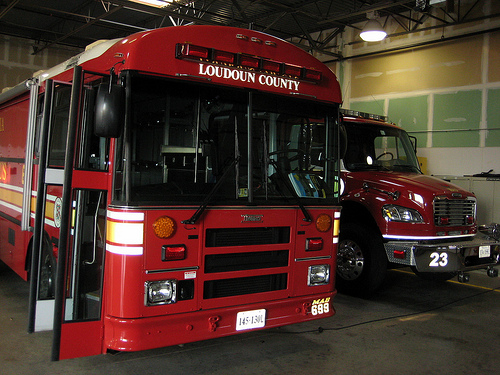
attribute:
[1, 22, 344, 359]
truck — parked, red, emergency vehicle, fire apparatus, vehicle, large, for  passengers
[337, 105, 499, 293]
truck — parked, red, emergency vehicle, fire apparatus, vehicle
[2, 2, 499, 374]
shed — fire station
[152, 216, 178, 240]
light — small, orange, emergency light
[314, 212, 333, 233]
light — emergency light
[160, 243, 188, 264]
light — emergency light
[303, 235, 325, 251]
light — emergency light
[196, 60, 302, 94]
letters — white, displayed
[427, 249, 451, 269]
number — 23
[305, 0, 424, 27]
rod — iron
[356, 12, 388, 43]
light — attached, on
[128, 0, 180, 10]
light — on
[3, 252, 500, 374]
floor — grey, partly road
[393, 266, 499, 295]
line — yellow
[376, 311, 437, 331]
line — yellow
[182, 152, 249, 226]
windshield wiper — black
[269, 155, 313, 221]
windshield wiper — black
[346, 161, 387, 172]
windshield wiper — black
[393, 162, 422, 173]
windshield wiper — black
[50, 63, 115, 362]
door — open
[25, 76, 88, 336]
door — open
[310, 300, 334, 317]
number — 699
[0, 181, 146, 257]
stripes — orange, white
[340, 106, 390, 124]
light — emergency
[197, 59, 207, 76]
letter — l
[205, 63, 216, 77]
letter — o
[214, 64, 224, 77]
letter — u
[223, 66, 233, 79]
letter — d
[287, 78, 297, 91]
letter — t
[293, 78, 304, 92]
letter — y